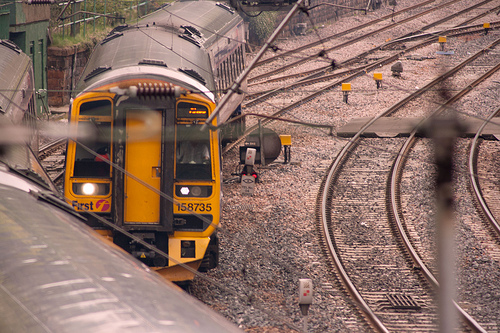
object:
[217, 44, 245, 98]
window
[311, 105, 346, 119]
floor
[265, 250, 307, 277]
rocks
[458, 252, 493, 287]
rocks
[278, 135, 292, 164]
bumps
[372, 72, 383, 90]
bumps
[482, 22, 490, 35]
bumps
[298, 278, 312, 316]
pole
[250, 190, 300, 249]
ground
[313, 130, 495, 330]
railway track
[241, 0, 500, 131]
railway track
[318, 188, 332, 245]
metal rod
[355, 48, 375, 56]
metal rod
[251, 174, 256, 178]
indicator light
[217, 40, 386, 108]
cables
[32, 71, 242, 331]
station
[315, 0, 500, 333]
railroad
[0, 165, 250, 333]
top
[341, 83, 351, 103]
bumps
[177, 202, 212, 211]
numbers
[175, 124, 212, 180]
windsheild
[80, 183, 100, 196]
train lights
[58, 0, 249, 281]
train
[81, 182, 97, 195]
lights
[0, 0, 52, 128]
hut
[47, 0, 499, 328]
train way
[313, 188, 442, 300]
track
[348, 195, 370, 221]
stone